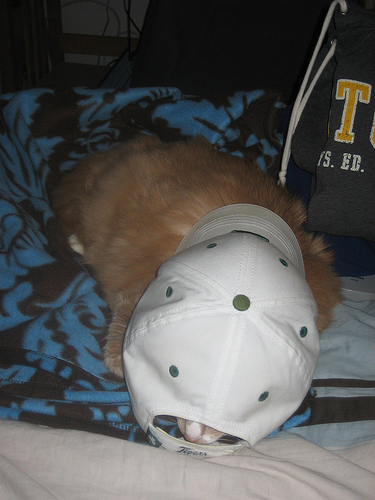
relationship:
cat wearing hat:
[54, 132, 345, 446] [121, 199, 323, 459]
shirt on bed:
[282, 2, 374, 239] [1, 84, 374, 499]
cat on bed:
[54, 132, 345, 446] [1, 84, 374, 499]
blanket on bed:
[1, 84, 316, 443] [1, 84, 374, 499]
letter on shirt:
[333, 77, 372, 145] [282, 2, 374, 239]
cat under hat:
[54, 132, 345, 446] [121, 199, 323, 459]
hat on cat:
[121, 199, 323, 459] [54, 132, 345, 446]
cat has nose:
[54, 132, 345, 446] [179, 419, 226, 446]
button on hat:
[232, 293, 252, 312] [121, 199, 323, 459]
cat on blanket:
[54, 132, 345, 446] [1, 84, 316, 443]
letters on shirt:
[318, 149, 367, 175] [282, 2, 374, 239]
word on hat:
[175, 445, 209, 459] [121, 199, 323, 459]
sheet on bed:
[1, 424, 374, 499] [1, 84, 374, 499]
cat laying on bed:
[54, 132, 345, 446] [1, 84, 374, 499]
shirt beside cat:
[282, 2, 374, 239] [54, 132, 345, 446]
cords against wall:
[99, 3, 141, 85] [42, 2, 149, 65]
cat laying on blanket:
[54, 132, 345, 446] [1, 84, 316, 443]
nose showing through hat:
[179, 419, 226, 446] [121, 199, 323, 459]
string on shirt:
[273, 0, 348, 186] [282, 2, 374, 239]